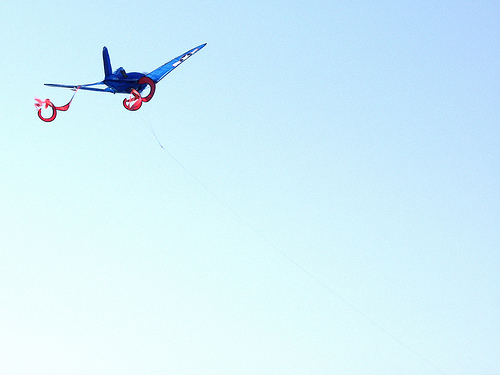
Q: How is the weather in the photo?
A: It is cloudy.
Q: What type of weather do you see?
A: It is cloudy.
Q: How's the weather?
A: It is cloudy.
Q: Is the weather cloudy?
A: Yes, it is cloudy.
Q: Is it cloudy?
A: Yes, it is cloudy.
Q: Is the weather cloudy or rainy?
A: It is cloudy.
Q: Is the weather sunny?
A: No, it is cloudy.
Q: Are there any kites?
A: Yes, there is a kite.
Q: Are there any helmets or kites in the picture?
A: Yes, there is a kite.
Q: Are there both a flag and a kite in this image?
A: Yes, there are both a kite and a flag.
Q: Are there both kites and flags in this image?
A: Yes, there are both a kite and a flag.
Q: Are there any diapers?
A: No, there are no diapers.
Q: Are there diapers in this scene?
A: No, there are no diapers.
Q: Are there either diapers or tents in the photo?
A: No, there are no diapers or tents.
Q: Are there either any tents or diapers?
A: No, there are no diapers or tents.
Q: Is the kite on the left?
A: Yes, the kite is on the left of the image.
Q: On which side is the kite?
A: The kite is on the left of the image.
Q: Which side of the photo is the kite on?
A: The kite is on the left of the image.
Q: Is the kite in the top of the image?
A: Yes, the kite is in the top of the image.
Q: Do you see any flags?
A: Yes, there is a flag.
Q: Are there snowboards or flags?
A: Yes, there is a flag.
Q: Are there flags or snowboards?
A: Yes, there is a flag.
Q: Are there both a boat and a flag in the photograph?
A: No, there is a flag but no boats.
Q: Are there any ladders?
A: No, there are no ladders.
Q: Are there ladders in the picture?
A: No, there are no ladders.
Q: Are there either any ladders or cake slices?
A: No, there are no ladders or cake slices.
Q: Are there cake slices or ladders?
A: No, there are no ladders or cake slices.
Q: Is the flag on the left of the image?
A: Yes, the flag is on the left of the image.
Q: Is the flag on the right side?
A: No, the flag is on the left of the image.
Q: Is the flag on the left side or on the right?
A: The flag is on the left of the image.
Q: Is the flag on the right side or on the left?
A: The flag is on the left of the image.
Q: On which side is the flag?
A: The flag is on the left of the image.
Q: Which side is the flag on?
A: The flag is on the left of the image.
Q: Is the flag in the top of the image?
A: Yes, the flag is in the top of the image.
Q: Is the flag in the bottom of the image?
A: No, the flag is in the top of the image.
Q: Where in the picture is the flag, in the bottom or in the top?
A: The flag is in the top of the image.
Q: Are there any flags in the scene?
A: Yes, there is a flag.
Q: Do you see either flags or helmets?
A: Yes, there is a flag.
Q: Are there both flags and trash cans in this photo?
A: No, there is a flag but no trash cans.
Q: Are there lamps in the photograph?
A: No, there are no lamps.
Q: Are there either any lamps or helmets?
A: No, there are no lamps or helmets.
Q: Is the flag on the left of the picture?
A: Yes, the flag is on the left of the image.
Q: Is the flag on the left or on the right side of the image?
A: The flag is on the left of the image.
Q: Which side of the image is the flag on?
A: The flag is on the left of the image.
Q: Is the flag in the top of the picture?
A: Yes, the flag is in the top of the image.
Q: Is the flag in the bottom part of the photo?
A: No, the flag is in the top of the image.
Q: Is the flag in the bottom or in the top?
A: The flag is in the top of the image.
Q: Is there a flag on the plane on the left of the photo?
A: Yes, there is a flag on the airplane.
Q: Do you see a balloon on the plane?
A: No, there is a flag on the plane.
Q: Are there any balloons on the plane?
A: No, there is a flag on the plane.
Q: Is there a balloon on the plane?
A: No, there is a flag on the plane.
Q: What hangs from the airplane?
A: The flag hangs from the plane.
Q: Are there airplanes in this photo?
A: Yes, there is an airplane.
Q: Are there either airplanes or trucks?
A: Yes, there is an airplane.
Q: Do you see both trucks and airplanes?
A: No, there is an airplane but no trucks.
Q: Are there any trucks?
A: No, there are no trucks.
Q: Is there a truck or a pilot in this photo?
A: No, there are no trucks or pilots.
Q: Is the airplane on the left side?
A: Yes, the airplane is on the left of the image.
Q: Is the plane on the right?
A: No, the plane is on the left of the image.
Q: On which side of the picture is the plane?
A: The plane is on the left of the image.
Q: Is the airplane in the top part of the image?
A: Yes, the airplane is in the top of the image.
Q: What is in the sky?
A: The plane is in the sky.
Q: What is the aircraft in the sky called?
A: The aircraft is an airplane.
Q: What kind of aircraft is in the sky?
A: The aircraft is an airplane.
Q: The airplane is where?
A: The airplane is in the sky.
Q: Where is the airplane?
A: The airplane is in the sky.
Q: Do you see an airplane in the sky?
A: Yes, there is an airplane in the sky.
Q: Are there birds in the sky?
A: No, there is an airplane in the sky.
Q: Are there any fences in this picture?
A: No, there are no fences.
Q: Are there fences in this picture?
A: No, there are no fences.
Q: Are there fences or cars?
A: No, there are no fences or cars.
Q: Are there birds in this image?
A: No, there are no birds.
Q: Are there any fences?
A: No, there are no fences.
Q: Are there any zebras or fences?
A: No, there are no fences or zebras.